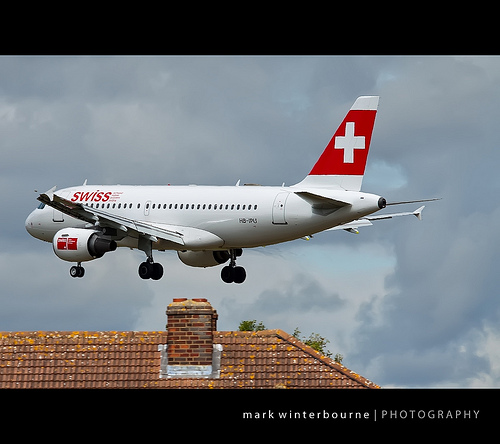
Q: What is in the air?
A: Plane.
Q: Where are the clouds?
A: In the sky.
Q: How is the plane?
A: In the air.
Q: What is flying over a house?
A: Swiss airlines plane.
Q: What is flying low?
A: Swiss airline plane.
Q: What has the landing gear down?
A: The plane.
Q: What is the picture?
A: Mark winterbourne photograph.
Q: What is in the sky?
A: Swiss airlines plane.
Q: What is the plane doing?
A: Flying over a neighborhood.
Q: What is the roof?
A: Brown and orange.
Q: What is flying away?
A: An airplane.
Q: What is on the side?
A: A big cloud.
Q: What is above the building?
A: Plane.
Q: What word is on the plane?
A: SWISS.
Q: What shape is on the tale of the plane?
A: Cross.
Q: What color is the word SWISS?
A: Red.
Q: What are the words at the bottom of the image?
A: Mark winterbourne photography.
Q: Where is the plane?
A: The sky.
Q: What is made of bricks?
A: The building.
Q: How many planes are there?
A: One.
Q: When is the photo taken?
A: Day time.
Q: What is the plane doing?
A: Flying.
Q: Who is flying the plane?
A: The pilot.